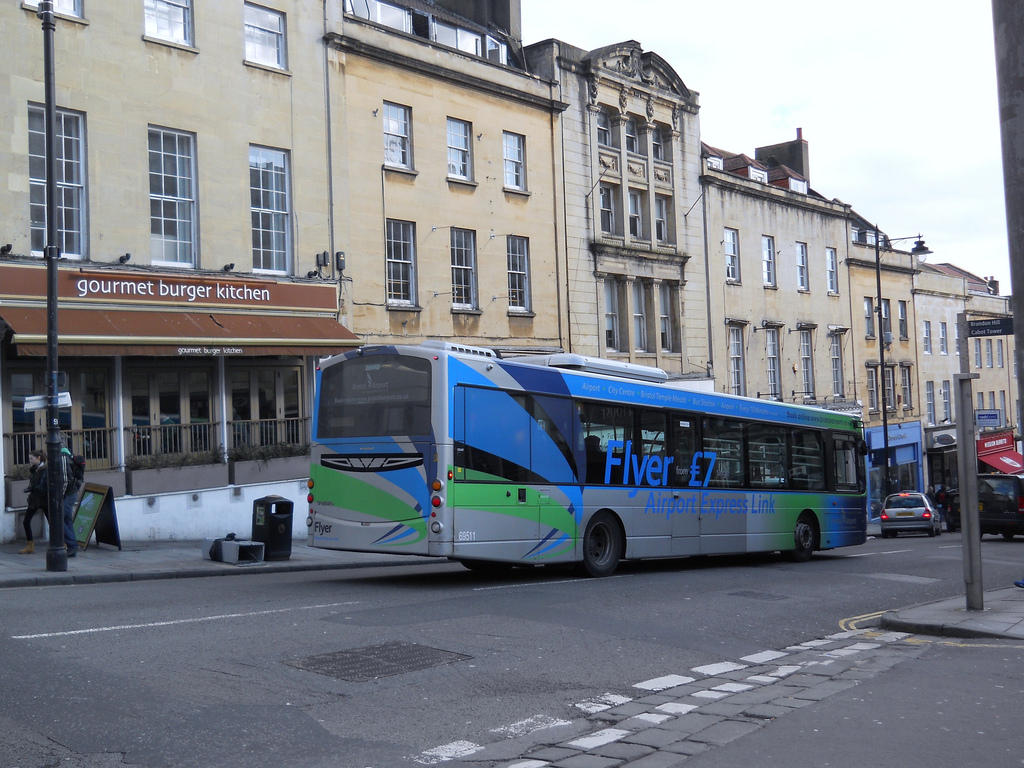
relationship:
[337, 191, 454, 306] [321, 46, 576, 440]
window on building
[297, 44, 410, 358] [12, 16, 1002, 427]
wall on side of building